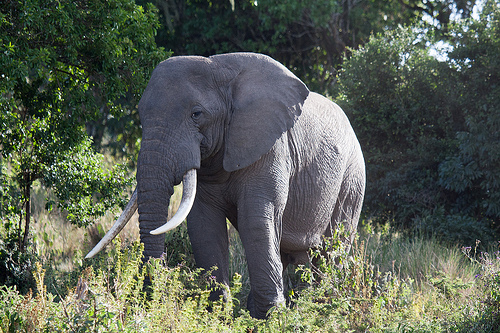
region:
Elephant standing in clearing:
[79, 48, 386, 320]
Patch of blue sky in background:
[397, 4, 496, 74]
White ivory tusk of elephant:
[146, 168, 201, 240]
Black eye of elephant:
[186, 106, 207, 123]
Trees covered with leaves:
[10, 3, 492, 146]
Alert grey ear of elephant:
[216, 52, 313, 172]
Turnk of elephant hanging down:
[129, 121, 179, 281]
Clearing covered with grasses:
[7, 208, 494, 327]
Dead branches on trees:
[288, 24, 360, 66]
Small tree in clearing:
[6, 100, 124, 290]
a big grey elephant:
[98, 61, 448, 254]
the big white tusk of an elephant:
[65, 161, 236, 288]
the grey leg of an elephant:
[238, 160, 310, 312]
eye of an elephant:
[156, 95, 222, 147]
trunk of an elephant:
[133, 151, 190, 298]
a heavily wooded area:
[36, 10, 496, 173]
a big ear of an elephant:
[222, 25, 363, 185]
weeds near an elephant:
[338, 217, 486, 319]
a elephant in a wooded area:
[75, 0, 381, 294]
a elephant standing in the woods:
[90, 47, 451, 292]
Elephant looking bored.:
[140, 69, 285, 258]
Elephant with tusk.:
[113, 68, 409, 330]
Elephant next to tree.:
[65, 70, 282, 272]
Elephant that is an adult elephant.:
[108, 78, 429, 329]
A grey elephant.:
[121, 83, 378, 314]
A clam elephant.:
[111, 85, 395, 319]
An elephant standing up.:
[128, 78, 382, 309]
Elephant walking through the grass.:
[126, 85, 383, 327]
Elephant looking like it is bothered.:
[120, 82, 395, 308]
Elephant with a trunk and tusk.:
[121, 87, 236, 294]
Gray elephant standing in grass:
[89, 50, 369, 326]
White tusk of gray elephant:
[150, 168, 198, 236]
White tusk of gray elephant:
[82, 190, 136, 259]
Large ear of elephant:
[214, 53, 311, 175]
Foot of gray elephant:
[237, 277, 292, 323]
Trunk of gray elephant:
[139, 153, 174, 261]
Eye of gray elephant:
[186, 106, 208, 119]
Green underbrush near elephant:
[31, 107, 122, 182]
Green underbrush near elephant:
[402, 123, 478, 214]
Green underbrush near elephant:
[360, 73, 426, 143]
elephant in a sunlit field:
[86, 53, 367, 320]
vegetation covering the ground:
[2, 218, 498, 332]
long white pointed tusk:
[84, 188, 141, 258]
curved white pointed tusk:
[150, 169, 200, 232]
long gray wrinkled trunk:
[138, 127, 175, 290]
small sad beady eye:
[188, 106, 204, 120]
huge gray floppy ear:
[211, 51, 311, 169]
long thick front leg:
[231, 176, 288, 318]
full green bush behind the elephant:
[319, 2, 498, 249]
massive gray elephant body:
[291, 92, 368, 249]